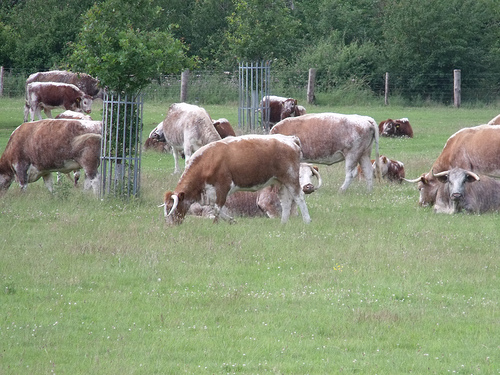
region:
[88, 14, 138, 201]
tree has a fence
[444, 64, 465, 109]
pole surrounds the back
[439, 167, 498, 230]
animal looking at the camera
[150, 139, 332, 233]
color of animal is brown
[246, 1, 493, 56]
many trees in background of photo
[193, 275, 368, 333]
white flowers in the grass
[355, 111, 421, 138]
animal is lying down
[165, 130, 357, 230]
animal is eating grass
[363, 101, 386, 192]
tail is long on animal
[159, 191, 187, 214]
horns on animal are white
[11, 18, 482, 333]
a herd of cows in a field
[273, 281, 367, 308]
some small white flowers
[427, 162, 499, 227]
a cow laying down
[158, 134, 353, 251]
a brown cow grazing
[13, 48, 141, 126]
a cow with it's baby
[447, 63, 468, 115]
a thick wood pole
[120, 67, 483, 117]
a long wire fence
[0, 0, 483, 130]
a background of trees and bushes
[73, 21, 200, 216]
a young, healthy tree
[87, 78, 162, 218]
a fence around a tree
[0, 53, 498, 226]
Animals in the pasture.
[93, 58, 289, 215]
Metal fences around the trees.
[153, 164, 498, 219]
Horns on the animals.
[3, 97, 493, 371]
Grassy field where animals are.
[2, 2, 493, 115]
Trees in the background.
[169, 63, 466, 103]
Wooden fence posts in the field.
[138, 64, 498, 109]
Metal fence along field.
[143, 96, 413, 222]
Cows laying in the field.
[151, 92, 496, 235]
Bulls in the field.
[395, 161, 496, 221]
Horned bulls laying in the field.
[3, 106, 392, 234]
four cows grazing in a field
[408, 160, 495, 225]
two cows laying down on ground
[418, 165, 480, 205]
two horns on a cow's head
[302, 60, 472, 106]
a wire fence with wooden poles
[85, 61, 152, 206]
a metal fence around a tree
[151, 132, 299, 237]
a cow eating grass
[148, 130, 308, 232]
a cow with its head down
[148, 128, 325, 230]
a cow grazing in a field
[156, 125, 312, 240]
a brown and white cow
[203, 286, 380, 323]
white flowers growing in a field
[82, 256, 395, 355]
the grass in the field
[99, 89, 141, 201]
the protector around the greenery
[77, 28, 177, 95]
the greenery hanging out of the top of the protector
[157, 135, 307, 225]
the bull grazing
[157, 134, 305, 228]
the bull with the head down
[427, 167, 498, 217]
the bull lying in the grass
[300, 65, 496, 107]
the fence in the back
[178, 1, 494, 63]
the trees in the back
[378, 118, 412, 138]
the darker cow lying in the back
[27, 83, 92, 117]
the shorter cow standing in front of the taller cow